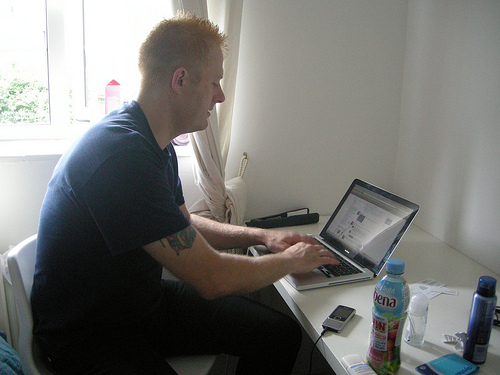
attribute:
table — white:
[239, 213, 499, 373]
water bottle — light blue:
[367, 256, 411, 374]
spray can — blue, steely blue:
[460, 275, 497, 365]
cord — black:
[306, 326, 328, 375]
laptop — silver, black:
[269, 177, 420, 292]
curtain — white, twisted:
[169, 1, 252, 228]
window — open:
[0, 0, 192, 150]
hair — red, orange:
[137, 14, 229, 73]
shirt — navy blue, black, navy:
[29, 97, 191, 335]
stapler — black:
[248, 205, 320, 227]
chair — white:
[5, 231, 220, 375]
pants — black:
[28, 278, 302, 373]